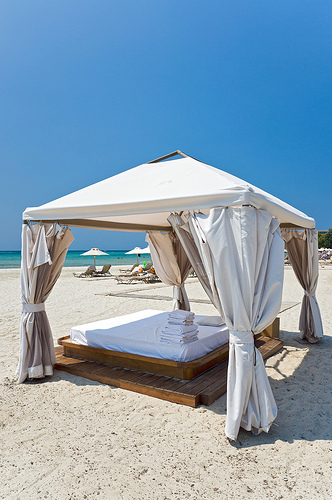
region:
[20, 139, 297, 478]
tent on beach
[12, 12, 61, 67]
white clouds in blue sky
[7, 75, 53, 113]
white clouds in blue sky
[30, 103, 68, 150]
white clouds in blue sky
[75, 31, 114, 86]
white clouds in blue sky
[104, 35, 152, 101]
white clouds in blue sky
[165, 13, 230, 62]
white clouds in blue sky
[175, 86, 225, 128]
white clouds in blue sky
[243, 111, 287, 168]
white clouds in blue sky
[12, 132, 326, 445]
a tent on the beach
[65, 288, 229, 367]
a mattress in the tent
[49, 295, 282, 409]
the mattress is on a platform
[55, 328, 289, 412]
the platform is wooden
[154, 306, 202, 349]
towels on the mattress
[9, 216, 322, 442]
the curtains are tied back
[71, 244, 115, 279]
an umbrella on the beach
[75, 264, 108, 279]
an empty chair under the umbrella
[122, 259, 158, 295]
people on chairs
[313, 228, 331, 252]
trees behind the tent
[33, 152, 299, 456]
tan colored tent in snad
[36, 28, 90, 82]
white clouds in blue sky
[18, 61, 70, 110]
white clouds in blue sky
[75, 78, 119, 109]
white clouds in blue sky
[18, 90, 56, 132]
white clouds in blue sky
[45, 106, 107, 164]
white clouds in blue sky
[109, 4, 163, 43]
white clouds in blue sky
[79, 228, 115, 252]
white clouds in blue sky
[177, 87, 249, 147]
white clouds in blue sky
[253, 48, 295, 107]
white clouds in blue sky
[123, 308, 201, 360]
white mattress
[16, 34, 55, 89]
white clouds in blue sky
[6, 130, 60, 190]
white clouds in blue sky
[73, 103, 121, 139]
white clouds in blue sky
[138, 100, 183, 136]
white clouds in blue sky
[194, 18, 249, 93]
white clouds in blue sky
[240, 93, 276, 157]
white clouds in blue sky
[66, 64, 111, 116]
white clouds in blue sky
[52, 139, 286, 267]
tent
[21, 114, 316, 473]
tent in sand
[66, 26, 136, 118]
white clouds in blue sky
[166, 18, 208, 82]
white clouds in blue sky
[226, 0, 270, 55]
white clouds in blue sky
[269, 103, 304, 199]
white clouds in blue sky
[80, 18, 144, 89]
white clouds in blue sky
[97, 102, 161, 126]
white clouds in blue sky